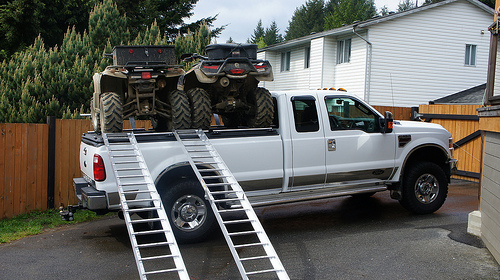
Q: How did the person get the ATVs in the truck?
A: Ramps.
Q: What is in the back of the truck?
A: ATVs.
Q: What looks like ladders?
A: Ramp.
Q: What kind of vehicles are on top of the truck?
A: Four wheelers.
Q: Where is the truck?
A: Driveway.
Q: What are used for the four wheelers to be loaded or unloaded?
A: Ladders.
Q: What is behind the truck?
A: Fence.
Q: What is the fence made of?
A: Wood.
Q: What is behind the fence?
A: Bushes.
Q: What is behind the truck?
A: House.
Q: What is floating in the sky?
A: Clouds.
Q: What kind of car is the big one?
A: Pickup truck.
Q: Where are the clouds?
A: In the sky.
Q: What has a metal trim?
A: The wooden gate.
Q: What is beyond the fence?
A: A white house.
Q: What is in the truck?
A: Two four wheelers.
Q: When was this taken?
A: Daytime.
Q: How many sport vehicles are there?
A: Two.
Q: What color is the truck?
A: White.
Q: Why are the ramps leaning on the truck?
A: To load and unload the sport vehicles.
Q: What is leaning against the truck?
A: Ramps.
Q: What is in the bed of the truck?
A: Two ATVs.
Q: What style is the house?
A: Two-story.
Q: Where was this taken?
A: A driveway.